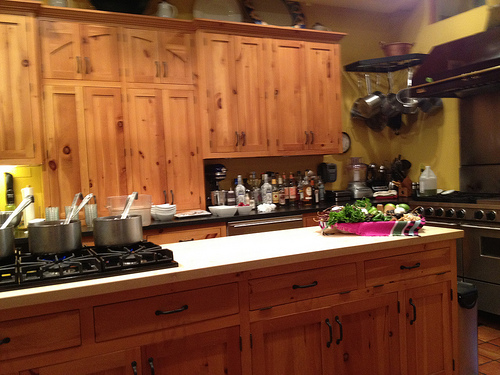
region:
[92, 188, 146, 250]
silver pot on stove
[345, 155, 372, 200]
Mixer on the counter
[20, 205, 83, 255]
Silver pot on the stove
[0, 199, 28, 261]
Silver pot on the stove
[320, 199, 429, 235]
Vegetables in a basket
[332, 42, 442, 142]
Pots hanging from ceiling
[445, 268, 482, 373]
Trash can near counter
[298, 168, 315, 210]
Glass bottle on counter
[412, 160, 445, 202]
Plastic jug on counter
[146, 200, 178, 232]
Stack of bowls on counter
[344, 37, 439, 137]
metal pots on rack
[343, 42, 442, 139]
metal pots hanging on rack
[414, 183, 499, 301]
stainless steel stove and oven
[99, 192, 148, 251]
stainless steel pot on burner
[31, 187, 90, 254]
stainless steel pot on burner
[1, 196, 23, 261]
stainless steel pot on burner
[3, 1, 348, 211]
natural wood cabinets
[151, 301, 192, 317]
black handle on cabinet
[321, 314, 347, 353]
black handles on cabinets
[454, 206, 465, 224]
black knob on stainless steel stove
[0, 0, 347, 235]
light colored wooden kitchen cabinets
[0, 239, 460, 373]
light colored wooden kitchen cabinets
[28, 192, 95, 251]
silver pot on the stove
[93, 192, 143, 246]
silver pot on the stove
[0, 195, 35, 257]
silver pot on the stove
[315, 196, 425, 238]
pink tray of vegetables on the counter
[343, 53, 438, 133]
pots and pans hanging on a rack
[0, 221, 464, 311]
a white counter top on wooden cabinets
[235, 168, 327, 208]
condiments on top of counter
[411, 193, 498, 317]
stainless steel stove in kitchen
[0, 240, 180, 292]
black over burners on cabinet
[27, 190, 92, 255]
a silver pot on the stove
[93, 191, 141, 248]
a silver pot on the stove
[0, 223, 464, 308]
white counter top on top of cabinets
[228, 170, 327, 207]
condiments on the counter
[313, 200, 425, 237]
a tray of vegetables on the counter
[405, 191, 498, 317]
a stainless steel stove in the kitchen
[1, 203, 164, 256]
three silver pots on stove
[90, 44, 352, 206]
the cabinets are closed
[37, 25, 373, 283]
the cabinets are closed